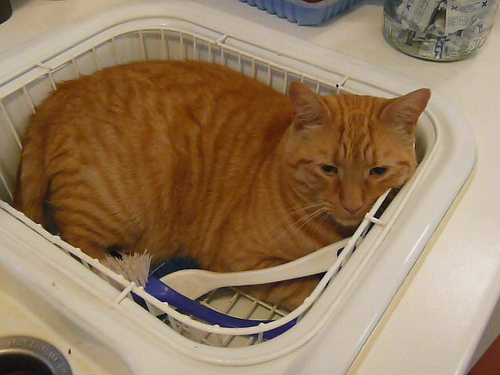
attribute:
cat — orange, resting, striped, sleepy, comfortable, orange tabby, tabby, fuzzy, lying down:
[11, 58, 435, 314]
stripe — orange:
[367, 95, 382, 165]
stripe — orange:
[333, 93, 347, 160]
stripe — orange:
[277, 164, 331, 245]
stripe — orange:
[68, 117, 144, 231]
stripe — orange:
[56, 214, 111, 242]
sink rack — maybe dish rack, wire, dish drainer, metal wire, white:
[2, 6, 446, 349]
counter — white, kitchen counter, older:
[1, 0, 499, 374]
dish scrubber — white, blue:
[136, 232, 359, 319]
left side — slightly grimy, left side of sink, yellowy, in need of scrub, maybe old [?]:
[0, 250, 140, 374]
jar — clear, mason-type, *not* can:
[379, 2, 497, 66]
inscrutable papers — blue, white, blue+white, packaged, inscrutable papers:
[385, 0, 492, 62]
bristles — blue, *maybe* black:
[134, 251, 201, 309]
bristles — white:
[88, 247, 168, 297]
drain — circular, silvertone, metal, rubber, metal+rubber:
[0, 329, 77, 373]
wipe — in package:
[441, 0, 474, 36]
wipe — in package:
[394, 0, 441, 35]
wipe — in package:
[477, 1, 494, 25]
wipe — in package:
[394, 23, 427, 48]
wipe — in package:
[418, 37, 445, 63]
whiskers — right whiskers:
[259, 196, 337, 253]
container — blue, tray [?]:
[225, 0, 365, 30]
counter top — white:
[1, 0, 499, 373]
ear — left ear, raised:
[376, 77, 433, 136]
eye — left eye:
[363, 159, 394, 182]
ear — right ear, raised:
[285, 77, 333, 136]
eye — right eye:
[317, 160, 340, 178]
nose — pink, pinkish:
[340, 203, 365, 215]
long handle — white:
[207, 231, 367, 292]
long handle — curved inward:
[157, 277, 301, 342]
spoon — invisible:
[494, 368, 498, 373]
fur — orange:
[11, 56, 433, 312]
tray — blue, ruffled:
[233, 0, 367, 30]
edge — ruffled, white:
[280, 1, 333, 28]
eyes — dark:
[316, 161, 389, 182]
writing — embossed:
[6, 335, 69, 373]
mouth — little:
[331, 213, 367, 222]